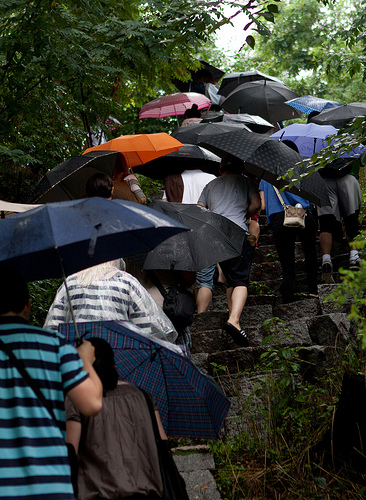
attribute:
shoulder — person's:
[153, 278, 174, 299]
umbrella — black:
[202, 123, 337, 210]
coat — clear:
[47, 259, 181, 347]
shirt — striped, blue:
[0, 314, 90, 498]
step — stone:
[189, 340, 343, 375]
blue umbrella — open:
[270, 120, 335, 151]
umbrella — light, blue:
[262, 119, 361, 157]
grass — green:
[208, 275, 363, 498]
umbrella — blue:
[284, 93, 352, 117]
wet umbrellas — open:
[112, 61, 337, 187]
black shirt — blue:
[2, 316, 83, 493]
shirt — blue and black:
[0, 326, 81, 492]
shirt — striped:
[192, 174, 273, 234]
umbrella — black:
[219, 76, 301, 123]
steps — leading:
[189, 210, 354, 444]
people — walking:
[78, 62, 346, 274]